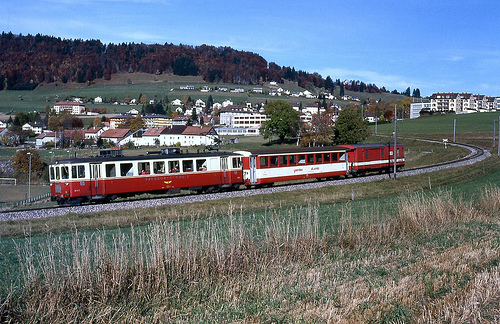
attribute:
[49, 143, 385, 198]
train — red, white , large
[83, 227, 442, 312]
grass — green, dry, Tall , brown  , sparse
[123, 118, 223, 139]
house — Large 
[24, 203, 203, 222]
gravel — gray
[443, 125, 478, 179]
rails — black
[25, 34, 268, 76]
trees — large, tall, dark, green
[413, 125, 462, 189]
track — empty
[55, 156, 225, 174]
windows — white, red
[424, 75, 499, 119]
buildings — white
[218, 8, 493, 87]
sky — blue, clear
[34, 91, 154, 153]
houses — small, pricey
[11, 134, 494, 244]
railroad track — long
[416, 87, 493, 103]
roof — red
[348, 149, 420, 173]
stripe — white